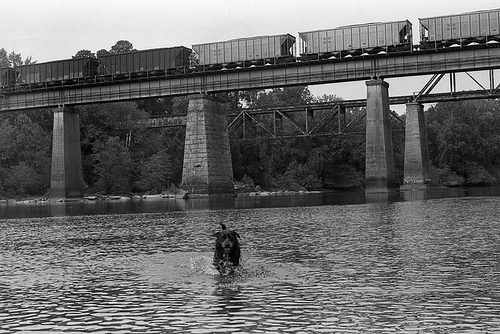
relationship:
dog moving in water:
[208, 219, 250, 280] [3, 185, 498, 331]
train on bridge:
[5, 7, 500, 89] [1, 39, 499, 115]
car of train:
[190, 31, 297, 73] [5, 7, 500, 89]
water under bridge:
[3, 185, 498, 331] [1, 39, 499, 115]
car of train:
[91, 42, 195, 82] [5, 7, 500, 89]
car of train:
[417, 6, 499, 51] [5, 7, 500, 89]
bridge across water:
[1, 39, 499, 115] [3, 185, 498, 331]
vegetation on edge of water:
[1, 36, 499, 190] [3, 185, 498, 331]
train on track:
[5, 7, 500, 89] [3, 40, 499, 98]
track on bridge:
[3, 40, 499, 98] [1, 39, 499, 115]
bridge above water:
[1, 39, 499, 115] [3, 185, 498, 331]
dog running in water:
[208, 219, 250, 280] [3, 185, 498, 331]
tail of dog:
[215, 219, 228, 229] [208, 219, 250, 280]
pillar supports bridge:
[179, 91, 241, 199] [1, 39, 499, 115]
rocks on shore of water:
[87, 191, 180, 202] [3, 185, 498, 331]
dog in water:
[208, 219, 250, 280] [3, 185, 498, 331]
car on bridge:
[190, 31, 297, 73] [1, 39, 499, 115]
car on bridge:
[91, 42, 195, 82] [1, 39, 499, 115]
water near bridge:
[3, 185, 498, 331] [1, 39, 499, 115]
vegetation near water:
[1, 36, 499, 190] [3, 185, 498, 331]